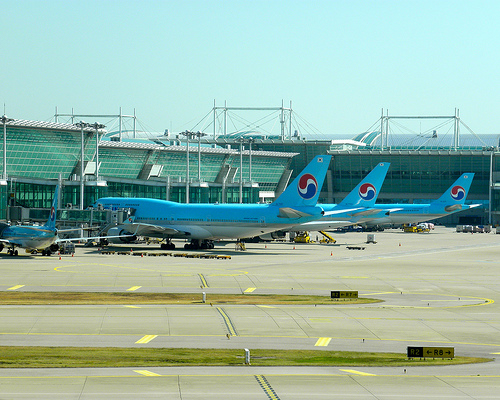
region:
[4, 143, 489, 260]
aircrafts in an airport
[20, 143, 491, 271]
aircrafts are color blue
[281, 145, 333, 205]
a logotype on vertical stabilizer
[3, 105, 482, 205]
building of airport is green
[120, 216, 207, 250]
left wing of aircraft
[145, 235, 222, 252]
wheels of aircraft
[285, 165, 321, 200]
logotype is color red, white and blue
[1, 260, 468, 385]
yellow lines on landing strip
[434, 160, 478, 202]
logotype on vertical stabilizer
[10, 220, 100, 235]
horizontal stabilizer of plane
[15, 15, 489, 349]
A view of an airport.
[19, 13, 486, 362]
Picture taken during the day.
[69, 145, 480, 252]
Three large planes.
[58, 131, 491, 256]
The planes are parked at the gates.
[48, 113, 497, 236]
The planes are at the terminal.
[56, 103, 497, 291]
The planes are very large.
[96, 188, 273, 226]
The plane is blue on the top.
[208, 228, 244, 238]
The plane is white on the bottom.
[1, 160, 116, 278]
A smaller plane is parked.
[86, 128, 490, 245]
The planes are not flying.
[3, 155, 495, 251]
line of four blue planes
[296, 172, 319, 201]
red, white and blue symbol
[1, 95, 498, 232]
green and silver building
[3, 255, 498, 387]
yellow lines in parking lot for planes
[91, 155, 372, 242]
bright light blue plane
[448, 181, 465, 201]
symbol on tail of plane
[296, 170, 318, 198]
red, white and blue logo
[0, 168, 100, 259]
part of blue plane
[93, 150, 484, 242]
three blue parked planes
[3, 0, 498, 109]
clear blue cloudless sky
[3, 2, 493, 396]
An airport scene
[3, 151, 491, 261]
These are passenger jets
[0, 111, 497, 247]
This is the airport terminal building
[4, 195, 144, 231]
A boarding gate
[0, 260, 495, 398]
These are airport taxiways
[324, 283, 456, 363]
These are runway marker signs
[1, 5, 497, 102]
The sky is clear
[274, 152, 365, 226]
The jet's tail section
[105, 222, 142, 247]
A jet engine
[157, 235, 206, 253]
The jet's rear landing gears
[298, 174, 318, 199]
Red white and blue logo on tail of plane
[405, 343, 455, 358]
Yellow and black sign on grass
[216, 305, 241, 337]
Yellow and black line on pavement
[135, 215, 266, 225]
Large group of windows on side of plane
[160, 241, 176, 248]
Wheels attached to landing gear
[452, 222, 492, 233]
Empty carts setting on pavement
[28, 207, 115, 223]
Long glass windows on jet bridge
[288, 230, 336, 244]
Yellow stairs leading to plane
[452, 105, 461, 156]
Two tall metal poles attached to building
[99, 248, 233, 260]
Line of empty cart carriers on runway